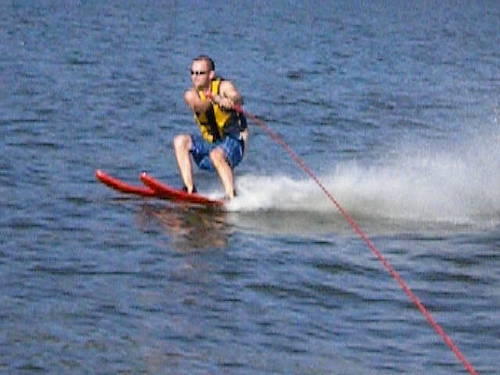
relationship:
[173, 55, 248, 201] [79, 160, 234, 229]
man on skis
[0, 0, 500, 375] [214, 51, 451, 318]
water in lake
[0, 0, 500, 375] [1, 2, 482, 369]
water in lake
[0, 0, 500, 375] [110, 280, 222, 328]
water in lake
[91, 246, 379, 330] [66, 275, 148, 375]
choppy water in lake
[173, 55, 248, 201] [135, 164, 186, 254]
man on water skies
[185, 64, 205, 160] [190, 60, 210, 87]
sunglasses on a face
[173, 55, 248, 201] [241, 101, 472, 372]
man holding rope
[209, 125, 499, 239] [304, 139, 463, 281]
water in air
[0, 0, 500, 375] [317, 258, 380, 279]
water calm with ripple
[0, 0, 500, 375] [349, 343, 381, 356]
water calm with ripple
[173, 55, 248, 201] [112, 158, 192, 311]
man water skiing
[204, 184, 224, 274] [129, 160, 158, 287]
ski boots hold man on skis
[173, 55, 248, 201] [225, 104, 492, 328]
man holding rope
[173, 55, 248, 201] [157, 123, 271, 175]
man wearing shorts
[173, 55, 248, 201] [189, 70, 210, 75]
man wearing sunglasses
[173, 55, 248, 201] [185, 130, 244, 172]
man wearing shorts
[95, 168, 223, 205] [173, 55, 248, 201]
red surfboard on man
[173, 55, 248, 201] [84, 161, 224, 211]
man riding on ski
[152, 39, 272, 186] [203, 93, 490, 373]
man holding rope